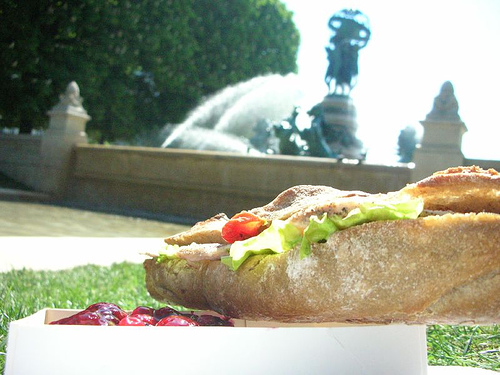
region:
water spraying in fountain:
[157, 72, 324, 150]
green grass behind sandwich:
[0, 260, 195, 373]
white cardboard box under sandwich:
[6, 305, 427, 372]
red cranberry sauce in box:
[48, 303, 235, 333]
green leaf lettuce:
[225, 196, 425, 268]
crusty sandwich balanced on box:
[145, 164, 499, 324]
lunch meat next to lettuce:
[178, 237, 232, 264]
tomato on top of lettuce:
[221, 211, 264, 242]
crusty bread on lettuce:
[164, 163, 499, 240]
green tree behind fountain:
[0, 2, 299, 145]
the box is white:
[22, 305, 102, 371]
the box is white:
[123, 283, 275, 370]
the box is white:
[220, 295, 341, 365]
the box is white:
[53, 285, 173, 372]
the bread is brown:
[134, 185, 466, 351]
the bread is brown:
[231, 160, 392, 314]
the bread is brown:
[147, 198, 307, 299]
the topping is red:
[74, 296, 238, 342]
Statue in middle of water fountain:
[323, 5, 370, 95]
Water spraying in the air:
[165, 72, 298, 154]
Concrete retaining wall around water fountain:
[89, 143, 249, 212]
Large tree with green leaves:
[0, 0, 298, 74]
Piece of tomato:
[220, 210, 264, 235]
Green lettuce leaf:
[304, 201, 423, 246]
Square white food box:
[7, 324, 434, 372]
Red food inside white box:
[55, 302, 234, 334]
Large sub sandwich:
[152, 164, 497, 324]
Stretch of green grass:
[0, 266, 143, 303]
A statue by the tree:
[326, 13, 371, 93]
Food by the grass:
[71, 165, 496, 325]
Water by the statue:
[160, 71, 304, 145]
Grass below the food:
[4, 193, 499, 363]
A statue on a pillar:
[429, 84, 460, 119]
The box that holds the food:
[8, 307, 426, 374]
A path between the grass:
[1, 234, 169, 269]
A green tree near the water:
[0, 2, 292, 128]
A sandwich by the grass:
[147, 189, 498, 324]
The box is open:
[8, 307, 428, 374]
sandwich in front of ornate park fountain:
[11, 11, 487, 361]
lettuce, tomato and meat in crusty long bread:
[140, 161, 492, 316]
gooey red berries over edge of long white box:
[2, 295, 423, 370]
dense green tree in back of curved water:
[5, 1, 311, 156]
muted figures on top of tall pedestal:
[297, 5, 368, 155]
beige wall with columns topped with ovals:
[2, 71, 494, 236]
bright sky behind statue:
[252, 0, 497, 165]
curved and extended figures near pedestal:
[270, 97, 310, 152]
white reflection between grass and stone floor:
[0, 190, 205, 310]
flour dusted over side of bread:
[281, 221, 447, 302]